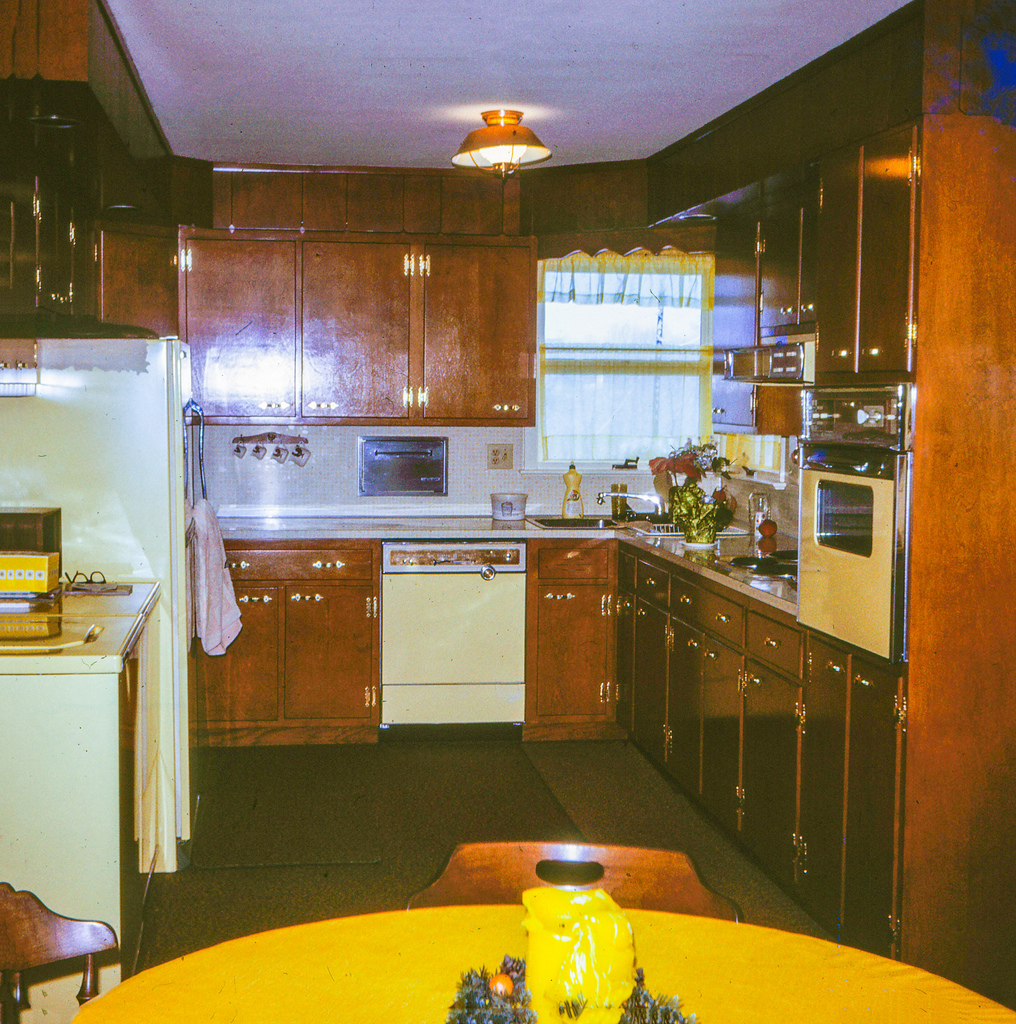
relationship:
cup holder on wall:
[221, 427, 316, 471] [192, 424, 365, 508]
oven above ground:
[306, 519, 591, 751] [106, 738, 855, 1016]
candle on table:
[519, 874, 648, 1014] [23, 881, 1013, 1021]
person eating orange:
[597, 765, 685, 873] [248, 768, 340, 843]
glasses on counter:
[60, 559, 113, 586] [14, 558, 148, 681]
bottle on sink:
[563, 462, 583, 520] [522, 496, 606, 540]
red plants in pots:
[652, 455, 743, 556] [642, 486, 741, 569]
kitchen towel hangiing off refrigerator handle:
[186, 501, 242, 649] [178, 507, 243, 565]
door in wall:
[355, 427, 452, 498] [333, 435, 478, 494]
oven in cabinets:
[381, 544, 525, 728] [354, 525, 551, 733]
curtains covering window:
[526, 244, 701, 470] [531, 257, 717, 495]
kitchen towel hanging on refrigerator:
[194, 499, 244, 657] [97, 320, 215, 857]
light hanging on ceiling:
[451, 104, 546, 186] [258, 41, 614, 98]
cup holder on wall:
[228, 432, 311, 467] [213, 433, 334, 514]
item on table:
[446, 859, 697, 1021] [67, 898, 1014, 1019]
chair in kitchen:
[4, 845, 185, 1007] [3, 2, 1015, 1019]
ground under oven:
[136, 733, 832, 973] [378, 537, 527, 736]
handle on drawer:
[703, 606, 736, 631] [692, 584, 751, 652]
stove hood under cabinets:
[720, 337, 815, 384] [658, 120, 972, 384]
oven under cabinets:
[796, 385, 909, 659] [632, 120, 986, 386]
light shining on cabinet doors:
[185, 327, 379, 419] [163, 216, 426, 434]